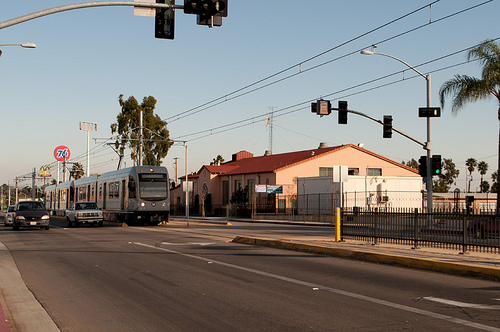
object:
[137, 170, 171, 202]
shield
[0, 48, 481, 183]
wires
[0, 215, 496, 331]
street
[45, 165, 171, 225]
train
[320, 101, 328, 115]
lights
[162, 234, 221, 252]
arrow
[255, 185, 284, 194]
signs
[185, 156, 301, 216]
businesses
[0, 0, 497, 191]
sky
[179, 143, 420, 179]
roof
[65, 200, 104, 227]
truck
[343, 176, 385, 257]
gate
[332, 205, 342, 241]
pole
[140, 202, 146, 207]
headlight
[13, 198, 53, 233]
cars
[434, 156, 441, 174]
light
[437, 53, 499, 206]
tree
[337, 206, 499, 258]
fence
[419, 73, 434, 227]
post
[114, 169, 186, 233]
trolly